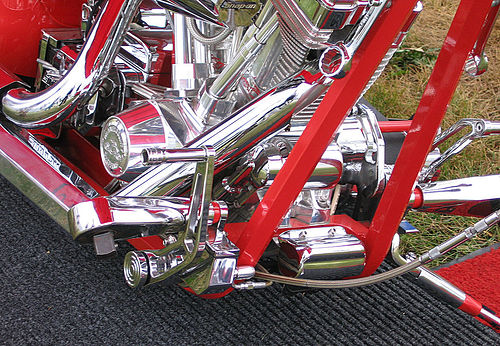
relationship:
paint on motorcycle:
[2, 0, 498, 297] [2, 2, 500, 330]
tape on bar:
[448, 287, 485, 318] [213, 11, 424, 276]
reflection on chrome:
[59, 51, 201, 149] [121, 36, 331, 174]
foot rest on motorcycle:
[105, 127, 235, 301] [2, 2, 500, 330]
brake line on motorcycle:
[255, 209, 498, 291] [2, 2, 500, 330]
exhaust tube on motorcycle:
[31, 0, 126, 130] [2, 2, 500, 330]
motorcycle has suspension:
[2, 2, 459, 282] [132, 12, 348, 200]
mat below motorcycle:
[0, 178, 497, 344] [2, 2, 500, 330]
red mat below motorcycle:
[423, 232, 498, 327] [2, 2, 500, 330]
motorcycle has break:
[2, 2, 500, 330] [121, 127, 237, 276]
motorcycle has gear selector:
[2, 2, 500, 330] [419, 117, 499, 183]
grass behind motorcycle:
[359, 0, 500, 269] [2, 2, 500, 330]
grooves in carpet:
[24, 249, 114, 332] [5, 296, 452, 343]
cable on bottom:
[258, 200, 495, 308] [253, 198, 498, 334]